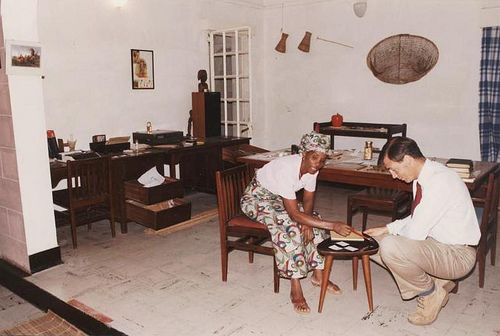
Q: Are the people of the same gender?
A: No, they are both male and female.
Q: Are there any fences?
A: No, there are no fences.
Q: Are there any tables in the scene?
A: Yes, there is a table.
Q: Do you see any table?
A: Yes, there is a table.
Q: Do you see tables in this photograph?
A: Yes, there is a table.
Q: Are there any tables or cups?
A: Yes, there is a table.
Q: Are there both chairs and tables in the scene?
A: Yes, there are both a table and a chair.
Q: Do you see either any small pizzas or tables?
A: Yes, there is a small table.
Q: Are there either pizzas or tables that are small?
A: Yes, the table is small.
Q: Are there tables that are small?
A: Yes, there is a small table.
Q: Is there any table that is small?
A: Yes, there is a table that is small.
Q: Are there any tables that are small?
A: Yes, there is a table that is small.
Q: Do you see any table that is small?
A: Yes, there is a table that is small.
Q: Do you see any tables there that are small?
A: Yes, there is a table that is small.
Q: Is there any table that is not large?
A: Yes, there is a small table.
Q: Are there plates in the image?
A: No, there are no plates.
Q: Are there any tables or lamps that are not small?
A: No, there is a table but it is small.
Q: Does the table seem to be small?
A: Yes, the table is small.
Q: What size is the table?
A: The table is small.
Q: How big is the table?
A: The table is small.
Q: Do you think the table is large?
A: No, the table is small.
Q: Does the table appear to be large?
A: No, the table is small.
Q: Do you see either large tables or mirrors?
A: No, there is a table but it is small.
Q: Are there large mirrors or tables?
A: No, there is a table but it is small.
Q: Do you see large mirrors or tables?
A: No, there is a table but it is small.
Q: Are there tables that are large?
A: No, there is a table but it is small.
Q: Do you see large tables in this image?
A: No, there is a table but it is small.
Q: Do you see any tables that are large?
A: No, there is a table but it is small.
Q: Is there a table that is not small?
A: No, there is a table but it is small.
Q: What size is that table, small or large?
A: The table is small.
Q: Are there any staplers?
A: No, there are no staplers.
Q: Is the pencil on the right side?
A: Yes, the pencil is on the right of the image.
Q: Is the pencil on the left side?
A: No, the pencil is on the right of the image.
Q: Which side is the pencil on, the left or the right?
A: The pencil is on the right of the image.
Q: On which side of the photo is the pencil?
A: The pencil is on the right of the image.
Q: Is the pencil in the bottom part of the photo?
A: Yes, the pencil is in the bottom of the image.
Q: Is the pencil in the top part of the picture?
A: No, the pencil is in the bottom of the image.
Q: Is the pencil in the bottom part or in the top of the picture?
A: The pencil is in the bottom of the image.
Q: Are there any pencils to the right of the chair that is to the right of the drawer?
A: Yes, there is a pencil to the right of the chair.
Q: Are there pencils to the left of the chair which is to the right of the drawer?
A: No, the pencil is to the right of the chair.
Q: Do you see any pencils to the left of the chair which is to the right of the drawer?
A: No, the pencil is to the right of the chair.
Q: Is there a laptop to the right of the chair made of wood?
A: No, there is a pencil to the right of the chair.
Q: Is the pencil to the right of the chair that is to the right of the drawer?
A: Yes, the pencil is to the right of the chair.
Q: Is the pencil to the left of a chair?
A: No, the pencil is to the right of a chair.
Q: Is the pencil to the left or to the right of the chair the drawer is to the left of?
A: The pencil is to the right of the chair.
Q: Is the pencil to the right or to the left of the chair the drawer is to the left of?
A: The pencil is to the right of the chair.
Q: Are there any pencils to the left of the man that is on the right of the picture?
A: Yes, there is a pencil to the left of the man.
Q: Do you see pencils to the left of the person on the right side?
A: Yes, there is a pencil to the left of the man.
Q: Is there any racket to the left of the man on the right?
A: No, there is a pencil to the left of the man.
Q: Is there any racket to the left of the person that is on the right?
A: No, there is a pencil to the left of the man.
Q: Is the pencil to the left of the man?
A: Yes, the pencil is to the left of the man.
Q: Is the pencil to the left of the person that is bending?
A: Yes, the pencil is to the left of the man.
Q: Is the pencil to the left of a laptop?
A: No, the pencil is to the left of the man.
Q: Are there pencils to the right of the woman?
A: Yes, there is a pencil to the right of the woman.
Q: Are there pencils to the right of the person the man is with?
A: Yes, there is a pencil to the right of the woman.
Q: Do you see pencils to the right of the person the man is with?
A: Yes, there is a pencil to the right of the woman.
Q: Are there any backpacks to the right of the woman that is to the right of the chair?
A: No, there is a pencil to the right of the woman.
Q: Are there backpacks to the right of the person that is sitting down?
A: No, there is a pencil to the right of the woman.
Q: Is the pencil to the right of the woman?
A: Yes, the pencil is to the right of the woman.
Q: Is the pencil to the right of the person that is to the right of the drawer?
A: Yes, the pencil is to the right of the woman.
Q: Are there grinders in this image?
A: No, there are no grinders.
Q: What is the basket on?
A: The basket is on the wall.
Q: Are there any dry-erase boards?
A: No, there are no dry-erase boards.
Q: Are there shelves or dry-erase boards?
A: No, there are no dry-erase boards or shelves.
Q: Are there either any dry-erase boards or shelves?
A: No, there are no dry-erase boards or shelves.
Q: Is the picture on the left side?
A: Yes, the picture is on the left of the image.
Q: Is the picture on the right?
A: No, the picture is on the left of the image.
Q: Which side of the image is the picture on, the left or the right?
A: The picture is on the left of the image.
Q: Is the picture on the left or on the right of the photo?
A: The picture is on the left of the image.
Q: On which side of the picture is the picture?
A: The picture is on the left of the image.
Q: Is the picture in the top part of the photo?
A: Yes, the picture is in the top of the image.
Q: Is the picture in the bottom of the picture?
A: No, the picture is in the top of the image.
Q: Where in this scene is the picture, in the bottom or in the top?
A: The picture is in the top of the image.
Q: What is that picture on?
A: The picture is on the wall.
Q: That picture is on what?
A: The picture is on the wall.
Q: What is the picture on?
A: The picture is on the wall.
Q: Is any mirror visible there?
A: No, there are no mirrors.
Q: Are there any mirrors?
A: No, there are no mirrors.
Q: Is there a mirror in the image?
A: No, there are no mirrors.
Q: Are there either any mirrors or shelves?
A: No, there are no mirrors or shelves.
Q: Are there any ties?
A: Yes, there is a tie.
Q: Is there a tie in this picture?
A: Yes, there is a tie.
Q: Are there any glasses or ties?
A: Yes, there is a tie.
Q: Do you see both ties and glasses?
A: No, there is a tie but no glasses.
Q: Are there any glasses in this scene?
A: No, there are no glasses.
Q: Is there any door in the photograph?
A: Yes, there is a door.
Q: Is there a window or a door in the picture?
A: Yes, there is a door.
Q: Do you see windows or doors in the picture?
A: Yes, there is a door.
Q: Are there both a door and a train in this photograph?
A: No, there is a door but no trains.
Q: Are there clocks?
A: No, there are no clocks.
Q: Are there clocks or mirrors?
A: No, there are no clocks or mirrors.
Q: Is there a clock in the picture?
A: No, there are no clocks.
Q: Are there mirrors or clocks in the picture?
A: No, there are no clocks or mirrors.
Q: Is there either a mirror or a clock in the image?
A: No, there are no clocks or mirrors.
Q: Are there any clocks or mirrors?
A: No, there are no clocks or mirrors.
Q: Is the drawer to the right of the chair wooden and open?
A: Yes, the drawer is wooden and open.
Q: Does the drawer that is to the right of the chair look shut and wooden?
A: No, the drawer is wooden but open.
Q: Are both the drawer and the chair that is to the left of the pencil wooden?
A: Yes, both the drawer and the chair are wooden.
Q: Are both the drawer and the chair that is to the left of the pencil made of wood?
A: Yes, both the drawer and the chair are made of wood.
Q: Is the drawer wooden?
A: Yes, the drawer is wooden.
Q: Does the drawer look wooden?
A: Yes, the drawer is wooden.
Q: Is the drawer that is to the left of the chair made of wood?
A: Yes, the drawer is made of wood.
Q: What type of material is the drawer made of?
A: The drawer is made of wood.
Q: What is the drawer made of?
A: The drawer is made of wood.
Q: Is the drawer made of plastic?
A: No, the drawer is made of wood.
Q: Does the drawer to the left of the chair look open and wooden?
A: Yes, the drawer is open and wooden.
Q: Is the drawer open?
A: Yes, the drawer is open.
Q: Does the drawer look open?
A: Yes, the drawer is open.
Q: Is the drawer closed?
A: No, the drawer is open.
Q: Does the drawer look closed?
A: No, the drawer is open.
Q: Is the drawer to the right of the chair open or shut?
A: The drawer is open.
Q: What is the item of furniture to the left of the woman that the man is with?
A: The piece of furniture is a drawer.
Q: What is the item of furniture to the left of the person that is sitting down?
A: The piece of furniture is a drawer.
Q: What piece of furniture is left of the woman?
A: The piece of furniture is a drawer.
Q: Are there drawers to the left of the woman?
A: Yes, there is a drawer to the left of the woman.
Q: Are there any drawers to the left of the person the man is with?
A: Yes, there is a drawer to the left of the woman.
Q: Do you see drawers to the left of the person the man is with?
A: Yes, there is a drawer to the left of the woman.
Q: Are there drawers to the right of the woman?
A: No, the drawer is to the left of the woman.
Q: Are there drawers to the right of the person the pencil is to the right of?
A: No, the drawer is to the left of the woman.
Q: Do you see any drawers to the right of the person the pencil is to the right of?
A: No, the drawer is to the left of the woman.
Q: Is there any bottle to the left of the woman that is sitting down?
A: No, there is a drawer to the left of the woman.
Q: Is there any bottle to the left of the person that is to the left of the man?
A: No, there is a drawer to the left of the woman.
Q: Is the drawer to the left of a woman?
A: Yes, the drawer is to the left of a woman.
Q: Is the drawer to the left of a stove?
A: No, the drawer is to the left of a woman.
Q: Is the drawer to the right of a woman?
A: No, the drawer is to the left of a woman.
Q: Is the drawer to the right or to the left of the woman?
A: The drawer is to the left of the woman.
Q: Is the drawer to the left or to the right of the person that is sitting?
A: The drawer is to the left of the woman.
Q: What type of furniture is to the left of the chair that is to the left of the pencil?
A: The piece of furniture is a drawer.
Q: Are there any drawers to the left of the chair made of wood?
A: Yes, there is a drawer to the left of the chair.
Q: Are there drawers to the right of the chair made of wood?
A: No, the drawer is to the left of the chair.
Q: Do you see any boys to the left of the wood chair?
A: No, there is a drawer to the left of the chair.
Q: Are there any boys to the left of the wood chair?
A: No, there is a drawer to the left of the chair.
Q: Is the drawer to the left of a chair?
A: Yes, the drawer is to the left of a chair.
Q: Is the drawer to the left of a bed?
A: No, the drawer is to the left of a chair.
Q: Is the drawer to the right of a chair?
A: No, the drawer is to the left of a chair.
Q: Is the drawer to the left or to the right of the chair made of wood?
A: The drawer is to the left of the chair.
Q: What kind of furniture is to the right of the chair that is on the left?
A: The piece of furniture is a drawer.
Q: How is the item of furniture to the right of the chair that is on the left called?
A: The piece of furniture is a drawer.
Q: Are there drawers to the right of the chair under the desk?
A: Yes, there is a drawer to the right of the chair.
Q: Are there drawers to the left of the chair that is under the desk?
A: No, the drawer is to the right of the chair.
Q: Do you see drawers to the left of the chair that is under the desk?
A: No, the drawer is to the right of the chair.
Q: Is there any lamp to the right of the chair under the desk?
A: No, there is a drawer to the right of the chair.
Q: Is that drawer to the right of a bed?
A: No, the drawer is to the right of a chair.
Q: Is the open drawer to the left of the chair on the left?
A: No, the drawer is to the right of the chair.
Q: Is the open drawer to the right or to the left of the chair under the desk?
A: The drawer is to the right of the chair.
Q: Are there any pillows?
A: No, there are no pillows.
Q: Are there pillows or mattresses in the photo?
A: No, there are no pillows or mattresses.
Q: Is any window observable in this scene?
A: Yes, there are windows.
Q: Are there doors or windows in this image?
A: Yes, there are windows.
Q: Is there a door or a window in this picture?
A: Yes, there are windows.